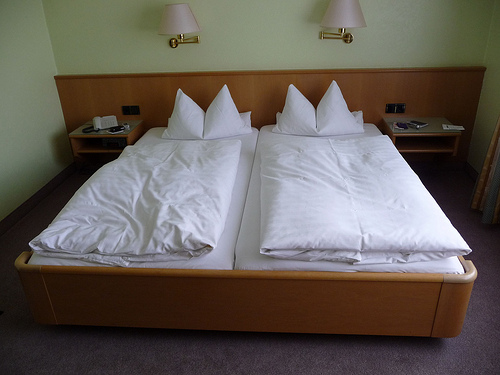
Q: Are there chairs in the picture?
A: No, there are no chairs.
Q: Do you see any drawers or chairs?
A: No, there are no chairs or drawers.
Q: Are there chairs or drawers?
A: No, there are no chairs or drawers.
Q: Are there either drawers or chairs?
A: No, there are no chairs or drawers.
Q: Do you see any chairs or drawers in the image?
A: No, there are no chairs or drawers.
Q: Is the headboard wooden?
A: Yes, the headboard is wooden.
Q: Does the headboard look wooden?
A: Yes, the headboard is wooden.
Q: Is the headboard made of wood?
A: Yes, the headboard is made of wood.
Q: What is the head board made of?
A: The head board is made of wood.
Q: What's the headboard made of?
A: The head board is made of wood.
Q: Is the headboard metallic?
A: No, the headboard is wooden.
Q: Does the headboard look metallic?
A: No, the headboard is wooden.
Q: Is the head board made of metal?
A: No, the head board is made of wood.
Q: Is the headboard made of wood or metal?
A: The headboard is made of wood.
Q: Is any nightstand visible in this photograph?
A: Yes, there is a nightstand.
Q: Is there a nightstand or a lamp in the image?
A: Yes, there is a nightstand.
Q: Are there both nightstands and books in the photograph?
A: Yes, there are both a nightstand and a book.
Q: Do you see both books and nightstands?
A: Yes, there are both a nightstand and a book.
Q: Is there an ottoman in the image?
A: No, there are no ottomen.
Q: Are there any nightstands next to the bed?
A: Yes, there is a nightstand next to the bed.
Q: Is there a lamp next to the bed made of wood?
A: No, there is a nightstand next to the bed.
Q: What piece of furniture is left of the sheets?
A: The piece of furniture is a nightstand.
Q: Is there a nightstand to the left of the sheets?
A: Yes, there is a nightstand to the left of the sheets.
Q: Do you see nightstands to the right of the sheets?
A: No, the nightstand is to the left of the sheets.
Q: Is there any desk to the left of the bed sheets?
A: No, there is a nightstand to the left of the sheets.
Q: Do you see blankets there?
A: Yes, there is a blanket.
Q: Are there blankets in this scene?
A: Yes, there is a blanket.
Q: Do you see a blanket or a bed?
A: Yes, there is a blanket.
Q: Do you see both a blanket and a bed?
A: Yes, there are both a blanket and a bed.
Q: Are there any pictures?
A: No, there are no pictures.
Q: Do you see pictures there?
A: No, there are no pictures.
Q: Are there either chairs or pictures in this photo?
A: No, there are no pictures or chairs.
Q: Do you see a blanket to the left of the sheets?
A: Yes, there is a blanket to the left of the sheets.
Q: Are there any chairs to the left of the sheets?
A: No, there is a blanket to the left of the sheets.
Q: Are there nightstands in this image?
A: Yes, there is a nightstand.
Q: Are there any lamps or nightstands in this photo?
A: Yes, there is a nightstand.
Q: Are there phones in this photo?
A: Yes, there is a phone.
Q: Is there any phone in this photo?
A: Yes, there is a phone.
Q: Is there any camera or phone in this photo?
A: Yes, there is a phone.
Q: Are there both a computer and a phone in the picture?
A: No, there is a phone but no computers.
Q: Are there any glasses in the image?
A: No, there are no glasses.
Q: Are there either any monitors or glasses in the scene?
A: No, there are no glasses or monitors.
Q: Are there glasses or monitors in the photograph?
A: No, there are no glasses or monitors.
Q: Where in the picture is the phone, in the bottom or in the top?
A: The phone is in the top of the image.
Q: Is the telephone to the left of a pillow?
A: Yes, the telephone is to the left of a pillow.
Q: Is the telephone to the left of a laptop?
A: No, the telephone is to the left of a pillow.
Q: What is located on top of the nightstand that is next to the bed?
A: The phone is on top of the nightstand.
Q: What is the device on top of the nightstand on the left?
A: The device is a phone.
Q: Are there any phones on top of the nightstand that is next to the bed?
A: Yes, there is a phone on top of the nightstand.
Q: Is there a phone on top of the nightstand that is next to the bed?
A: Yes, there is a phone on top of the nightstand.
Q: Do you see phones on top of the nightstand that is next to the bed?
A: Yes, there is a phone on top of the nightstand.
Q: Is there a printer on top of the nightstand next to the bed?
A: No, there is a phone on top of the nightstand.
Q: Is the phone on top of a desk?
A: No, the phone is on top of the nightstand.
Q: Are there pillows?
A: Yes, there are pillows.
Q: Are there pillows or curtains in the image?
A: Yes, there are pillows.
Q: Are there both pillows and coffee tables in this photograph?
A: No, there are pillows but no coffee tables.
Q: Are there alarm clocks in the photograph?
A: No, there are no alarm clocks.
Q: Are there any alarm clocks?
A: No, there are no alarm clocks.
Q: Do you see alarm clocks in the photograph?
A: No, there are no alarm clocks.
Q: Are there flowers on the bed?
A: No, there are pillows on the bed.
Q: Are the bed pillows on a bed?
A: Yes, the pillows are on a bed.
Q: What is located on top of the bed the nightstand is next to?
A: The pillows are on top of the bed.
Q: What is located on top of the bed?
A: The pillows are on top of the bed.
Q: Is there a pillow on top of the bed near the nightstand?
A: Yes, there are pillows on top of the bed.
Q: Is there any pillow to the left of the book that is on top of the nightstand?
A: Yes, there are pillows to the left of the book.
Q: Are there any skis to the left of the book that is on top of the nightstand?
A: No, there are pillows to the left of the book.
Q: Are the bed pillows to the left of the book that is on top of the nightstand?
A: Yes, the pillows are to the left of the book.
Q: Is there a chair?
A: No, there are no chairs.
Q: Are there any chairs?
A: No, there are no chairs.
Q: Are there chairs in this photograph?
A: No, there are no chairs.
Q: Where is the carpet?
A: The carpet is on the floor.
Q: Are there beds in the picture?
A: Yes, there is a bed.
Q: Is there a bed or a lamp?
A: Yes, there is a bed.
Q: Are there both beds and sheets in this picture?
A: Yes, there are both a bed and a sheet.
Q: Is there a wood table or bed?
A: Yes, there is a wood bed.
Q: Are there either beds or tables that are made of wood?
A: Yes, the bed is made of wood.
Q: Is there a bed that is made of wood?
A: Yes, there is a bed that is made of wood.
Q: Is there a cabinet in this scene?
A: No, there are no cabinets.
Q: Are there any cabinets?
A: No, there are no cabinets.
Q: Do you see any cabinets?
A: No, there are no cabinets.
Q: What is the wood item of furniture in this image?
A: The piece of furniture is a bed.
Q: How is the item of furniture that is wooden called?
A: The piece of furniture is a bed.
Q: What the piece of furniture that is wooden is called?
A: The piece of furniture is a bed.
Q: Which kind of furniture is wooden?
A: The furniture is a bed.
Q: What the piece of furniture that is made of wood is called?
A: The piece of furniture is a bed.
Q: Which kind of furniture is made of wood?
A: The furniture is a bed.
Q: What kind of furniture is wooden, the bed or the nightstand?
A: The bed is wooden.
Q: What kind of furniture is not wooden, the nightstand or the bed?
A: The nightstand is not wooden.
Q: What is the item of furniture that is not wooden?
A: The piece of furniture is a nightstand.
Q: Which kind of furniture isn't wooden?
A: The furniture is a nightstand.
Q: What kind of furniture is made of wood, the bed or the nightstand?
A: The bed is made of wood.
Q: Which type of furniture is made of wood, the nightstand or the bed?
A: The bed is made of wood.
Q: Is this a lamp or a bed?
A: This is a bed.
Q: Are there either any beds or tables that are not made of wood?
A: No, there is a bed but it is made of wood.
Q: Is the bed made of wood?
A: Yes, the bed is made of wood.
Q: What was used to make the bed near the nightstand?
A: The bed is made of wood.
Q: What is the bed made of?
A: The bed is made of wood.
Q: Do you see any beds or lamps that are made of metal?
A: No, there is a bed but it is made of wood.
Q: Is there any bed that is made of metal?
A: No, there is a bed but it is made of wood.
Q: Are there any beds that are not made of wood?
A: No, there is a bed but it is made of wood.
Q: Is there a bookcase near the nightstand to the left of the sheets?
A: No, there is a bed near the nightstand.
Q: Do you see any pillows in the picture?
A: Yes, there is a pillow.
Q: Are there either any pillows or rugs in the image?
A: Yes, there is a pillow.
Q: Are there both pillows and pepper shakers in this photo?
A: No, there is a pillow but no pepper shakers.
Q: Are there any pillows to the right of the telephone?
A: Yes, there is a pillow to the right of the telephone.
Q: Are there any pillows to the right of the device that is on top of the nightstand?
A: Yes, there is a pillow to the right of the telephone.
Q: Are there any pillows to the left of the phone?
A: No, the pillow is to the right of the phone.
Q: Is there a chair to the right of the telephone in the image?
A: No, there is a pillow to the right of the telephone.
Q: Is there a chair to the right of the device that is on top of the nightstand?
A: No, there is a pillow to the right of the telephone.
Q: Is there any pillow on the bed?
A: Yes, there is a pillow on the bed.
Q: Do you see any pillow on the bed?
A: Yes, there is a pillow on the bed.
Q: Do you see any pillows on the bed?
A: Yes, there is a pillow on the bed.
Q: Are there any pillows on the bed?
A: Yes, there is a pillow on the bed.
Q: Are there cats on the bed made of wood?
A: No, there is a pillow on the bed.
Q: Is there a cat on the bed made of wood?
A: No, there is a pillow on the bed.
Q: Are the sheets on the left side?
A: No, the sheets are on the right of the image.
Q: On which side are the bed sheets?
A: The sheets are on the right of the image.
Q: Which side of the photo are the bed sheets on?
A: The sheets are on the right of the image.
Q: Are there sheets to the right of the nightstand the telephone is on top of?
A: Yes, there are sheets to the right of the nightstand.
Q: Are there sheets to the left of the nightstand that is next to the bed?
A: No, the sheets are to the right of the nightstand.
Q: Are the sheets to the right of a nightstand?
A: Yes, the sheets are to the right of a nightstand.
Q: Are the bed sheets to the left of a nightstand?
A: No, the sheets are to the right of a nightstand.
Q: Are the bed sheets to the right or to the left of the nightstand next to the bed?
A: The sheets are to the right of the nightstand.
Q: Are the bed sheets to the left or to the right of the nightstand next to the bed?
A: The sheets are to the right of the nightstand.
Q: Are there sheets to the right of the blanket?
A: Yes, there are sheets to the right of the blanket.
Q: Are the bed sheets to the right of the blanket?
A: Yes, the sheets are to the right of the blanket.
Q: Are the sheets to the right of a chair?
A: No, the sheets are to the right of the blanket.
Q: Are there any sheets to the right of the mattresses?
A: Yes, there are sheets to the right of the mattresses.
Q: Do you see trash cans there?
A: No, there are no trash cans.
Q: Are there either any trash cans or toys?
A: No, there are no trash cans or toys.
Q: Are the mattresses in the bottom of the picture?
A: Yes, the mattresses are in the bottom of the image.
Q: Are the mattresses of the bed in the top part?
A: No, the mattresses are in the bottom of the image.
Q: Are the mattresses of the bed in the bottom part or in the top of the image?
A: The mattresses are in the bottom of the image.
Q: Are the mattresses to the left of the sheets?
A: Yes, the mattresses are to the left of the sheets.